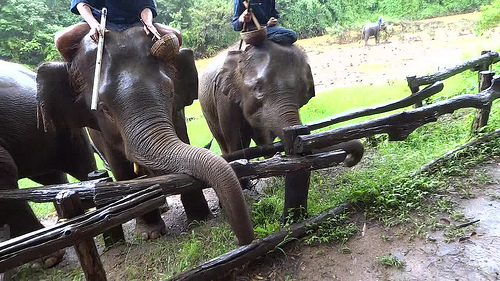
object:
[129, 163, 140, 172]
tusk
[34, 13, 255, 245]
elephant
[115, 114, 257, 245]
trunk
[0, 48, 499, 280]
fence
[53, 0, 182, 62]
people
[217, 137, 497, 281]
bare ground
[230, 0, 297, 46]
people